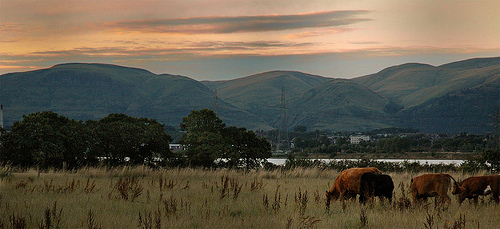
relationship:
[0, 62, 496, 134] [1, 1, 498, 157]
mountains in background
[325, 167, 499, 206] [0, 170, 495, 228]
animals in field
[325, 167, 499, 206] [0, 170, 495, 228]
cows in pasture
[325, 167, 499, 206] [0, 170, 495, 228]
cows in field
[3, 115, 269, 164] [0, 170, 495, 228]
trees by field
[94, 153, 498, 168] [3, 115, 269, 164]
water behind trees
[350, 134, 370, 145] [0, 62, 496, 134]
buildings by mountains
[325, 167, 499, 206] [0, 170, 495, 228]
cows in grass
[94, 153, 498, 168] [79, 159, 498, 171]
water behind bushes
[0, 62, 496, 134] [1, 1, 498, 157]
mountains on horizon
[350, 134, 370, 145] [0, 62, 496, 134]
building by mountain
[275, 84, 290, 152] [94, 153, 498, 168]
tower behind water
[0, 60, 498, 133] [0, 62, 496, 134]
range of mountains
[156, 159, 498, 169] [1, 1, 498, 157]
lake in background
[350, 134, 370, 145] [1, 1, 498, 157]
house in background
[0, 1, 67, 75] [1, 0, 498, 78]
sunset in sky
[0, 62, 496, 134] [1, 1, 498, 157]
hills in distance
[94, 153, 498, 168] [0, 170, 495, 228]
river bordering field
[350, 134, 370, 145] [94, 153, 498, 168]
building across river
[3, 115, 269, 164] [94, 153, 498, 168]
trees by river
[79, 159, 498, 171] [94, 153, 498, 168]
bushes by river